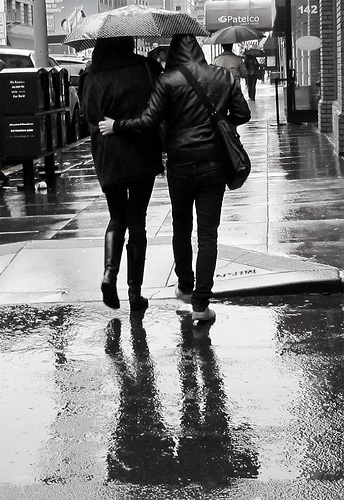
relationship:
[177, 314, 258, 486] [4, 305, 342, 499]
shadows on road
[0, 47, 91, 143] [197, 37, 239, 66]
cars on street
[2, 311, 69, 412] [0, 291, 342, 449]
puddle on street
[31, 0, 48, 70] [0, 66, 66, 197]
pole behind dispenser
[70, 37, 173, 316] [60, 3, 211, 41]
person under umbrella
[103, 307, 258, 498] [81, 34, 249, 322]
reflection of pedestrians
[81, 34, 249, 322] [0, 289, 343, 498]
pedestrians in street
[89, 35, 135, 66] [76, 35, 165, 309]
head of a person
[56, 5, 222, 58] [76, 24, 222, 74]
umbrella over heads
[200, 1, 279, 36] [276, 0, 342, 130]
awning on building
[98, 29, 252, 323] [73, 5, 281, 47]
pedestrians under umbrellas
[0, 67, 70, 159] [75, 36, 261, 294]
boxes left of people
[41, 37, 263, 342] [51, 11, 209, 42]
couple holding umbrella